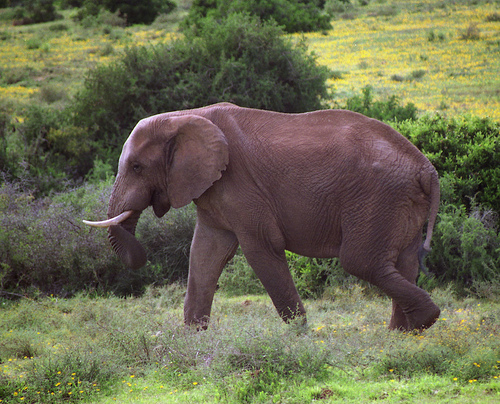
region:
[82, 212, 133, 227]
A white elephant tusk.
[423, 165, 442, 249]
A grey elephant tail.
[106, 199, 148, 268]
A grey elephant trunk.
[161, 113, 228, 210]
An elephants left giant ear.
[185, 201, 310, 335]
Two front grey elephant legs.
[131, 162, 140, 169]
Black eye of an elephant.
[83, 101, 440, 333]
A large grey elephant walking.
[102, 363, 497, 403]
The brightest green grass around an elephant.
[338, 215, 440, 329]
Two back grey elephant legs.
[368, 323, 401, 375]
part of a twig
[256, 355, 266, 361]
part of a forest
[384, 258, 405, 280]
edge of a leg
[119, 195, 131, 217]
part of a trunk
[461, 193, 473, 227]
part of a forest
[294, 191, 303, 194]
side of an elephant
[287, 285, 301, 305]
part of an elephant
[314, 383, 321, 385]
part of a bush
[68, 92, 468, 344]
the elephant is walkning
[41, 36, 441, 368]
the elephant is brown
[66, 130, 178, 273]
the elephant has tusks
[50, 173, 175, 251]
the tusk is white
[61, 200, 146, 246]
the tusk has a pointy tip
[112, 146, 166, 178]
the eye is open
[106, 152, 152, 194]
the eye is black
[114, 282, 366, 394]
the grass is wild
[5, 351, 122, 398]
small flowers in the grass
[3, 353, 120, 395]
the flowers are yellow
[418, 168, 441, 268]
the tail of an elephant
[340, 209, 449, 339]
an uplifted hind leg on an elephant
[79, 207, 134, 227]
the white tusk of an elephant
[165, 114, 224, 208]
the large ear of an elephant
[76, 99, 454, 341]
an elephant walking in the grass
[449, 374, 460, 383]
a yellow flower in the grass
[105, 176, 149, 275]
the trunk of an elephant curled up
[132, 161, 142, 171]
the eye of an elephant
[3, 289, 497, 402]
grass around an elephant's feet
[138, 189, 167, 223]
the open mouth of an elephant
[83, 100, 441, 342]
A large elephant.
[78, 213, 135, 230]
The elephant's white tusk.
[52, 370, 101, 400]
A group of small yellow flowers.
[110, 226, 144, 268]
Part of the elephant's trunk.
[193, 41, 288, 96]
Part of a large green bush.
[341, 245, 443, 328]
The elephant's back legs.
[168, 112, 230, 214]
The elephant's ear.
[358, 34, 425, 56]
Part of a grassy field.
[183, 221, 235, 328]
The elephant's front leg.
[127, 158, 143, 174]
The elephant's eye.